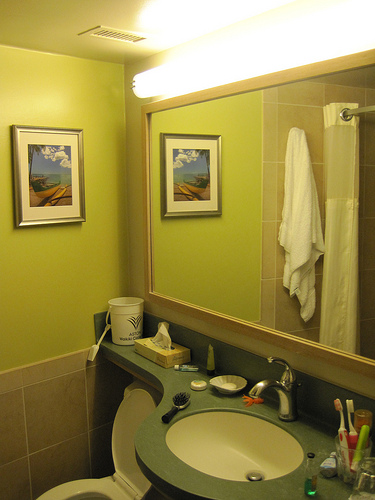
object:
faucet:
[248, 357, 298, 422]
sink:
[165, 408, 304, 482]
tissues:
[151, 322, 172, 351]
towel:
[278, 127, 326, 323]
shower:
[267, 78, 373, 370]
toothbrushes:
[333, 398, 350, 469]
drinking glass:
[342, 457, 375, 497]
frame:
[9, 123, 87, 227]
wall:
[2, 60, 130, 374]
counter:
[99, 335, 372, 500]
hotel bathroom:
[0, 0, 373, 500]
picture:
[11, 123, 86, 228]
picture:
[158, 131, 222, 220]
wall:
[149, 80, 374, 361]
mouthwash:
[304, 452, 318, 495]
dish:
[209, 374, 248, 395]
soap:
[221, 383, 237, 390]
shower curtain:
[317, 103, 361, 358]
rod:
[343, 102, 374, 117]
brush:
[161, 391, 191, 423]